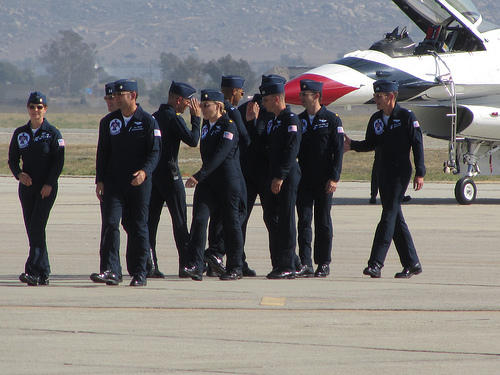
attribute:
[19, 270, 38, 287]
shoe — black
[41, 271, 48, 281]
shoe — black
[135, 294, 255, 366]
floor — gray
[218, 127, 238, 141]
patch — flag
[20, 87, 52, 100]
hat — blue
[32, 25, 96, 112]
tree — large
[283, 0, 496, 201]
jet — red, black, white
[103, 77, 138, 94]
caps — dark blue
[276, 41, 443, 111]
nose — red, white, blue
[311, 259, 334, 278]
shoe — black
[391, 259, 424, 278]
shoe — black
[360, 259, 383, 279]
shoe — black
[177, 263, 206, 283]
shoe — black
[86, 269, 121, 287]
shoe — black